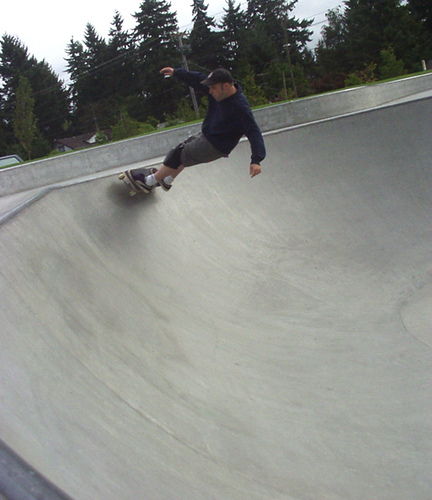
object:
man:
[124, 68, 266, 194]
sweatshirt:
[173, 63, 266, 165]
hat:
[200, 68, 233, 87]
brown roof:
[58, 129, 113, 150]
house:
[56, 127, 113, 156]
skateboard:
[118, 168, 172, 197]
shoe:
[128, 168, 154, 194]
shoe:
[150, 167, 174, 192]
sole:
[149, 169, 168, 192]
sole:
[129, 169, 150, 193]